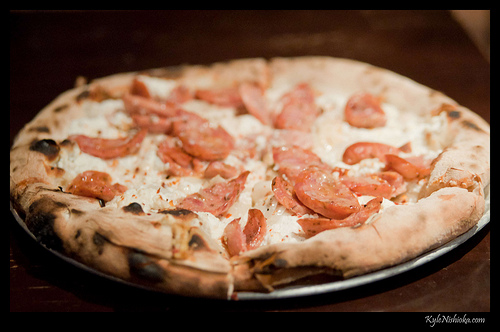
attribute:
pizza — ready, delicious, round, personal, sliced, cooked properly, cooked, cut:
[14, 54, 497, 301]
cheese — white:
[63, 75, 450, 253]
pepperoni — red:
[66, 78, 431, 258]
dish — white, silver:
[8, 168, 490, 300]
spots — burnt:
[12, 89, 345, 301]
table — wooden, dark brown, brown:
[12, 11, 493, 313]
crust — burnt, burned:
[8, 56, 490, 299]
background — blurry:
[9, 9, 493, 312]